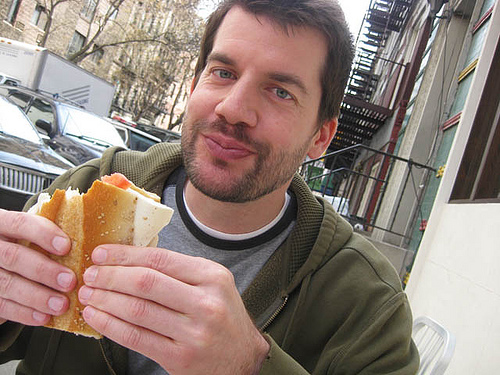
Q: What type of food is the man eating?
A: A sandwich.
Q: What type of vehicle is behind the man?
A: A car.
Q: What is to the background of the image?
A: Car.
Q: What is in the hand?
A: Food.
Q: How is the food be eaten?
A: Mouth.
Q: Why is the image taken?
A: Remembrance.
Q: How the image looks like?
A: Good.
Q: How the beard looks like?
A: Trim.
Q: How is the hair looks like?
A: Short.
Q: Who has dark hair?
A: The man.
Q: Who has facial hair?
A: The man.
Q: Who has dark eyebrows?
A: The man.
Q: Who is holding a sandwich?
A: The man.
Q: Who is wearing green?
A: The man.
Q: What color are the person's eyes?
A: Blue.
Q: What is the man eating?
A: Sandwich.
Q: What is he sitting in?
A: Chair.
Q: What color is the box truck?
A: White.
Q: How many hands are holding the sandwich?
A: Two.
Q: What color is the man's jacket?
A: Green.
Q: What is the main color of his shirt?
A: Gray.